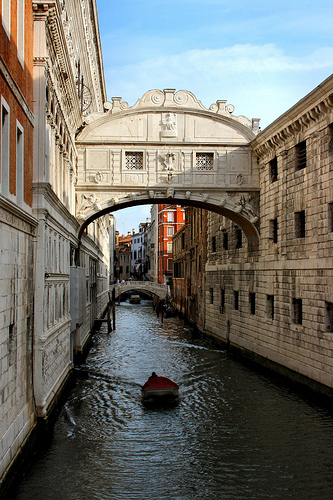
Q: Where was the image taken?
A: It was taken at the city.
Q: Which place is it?
A: It is a city.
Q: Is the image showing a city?
A: Yes, it is showing a city.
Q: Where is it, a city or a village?
A: It is a city.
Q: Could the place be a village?
A: No, it is a city.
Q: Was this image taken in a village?
A: No, the picture was taken in a city.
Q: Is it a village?
A: No, it is a city.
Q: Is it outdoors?
A: Yes, it is outdoors.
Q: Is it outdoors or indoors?
A: It is outdoors.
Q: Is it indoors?
A: No, it is outdoors.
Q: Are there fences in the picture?
A: No, there are no fences.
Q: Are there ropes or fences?
A: No, there are no fences or ropes.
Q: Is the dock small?
A: Yes, the dock is small.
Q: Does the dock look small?
A: Yes, the dock is small.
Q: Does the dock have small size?
A: Yes, the dock is small.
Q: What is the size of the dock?
A: The dock is small.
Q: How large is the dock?
A: The dock is small.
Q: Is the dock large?
A: No, the dock is small.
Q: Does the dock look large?
A: No, the dock is small.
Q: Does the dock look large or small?
A: The dock is small.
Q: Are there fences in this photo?
A: No, there are no fences.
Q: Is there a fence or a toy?
A: No, there are no fences or toys.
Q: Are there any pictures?
A: No, there are no pictures.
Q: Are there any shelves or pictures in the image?
A: No, there are no pictures or shelves.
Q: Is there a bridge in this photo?
A: Yes, there is a bridge.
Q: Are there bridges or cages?
A: Yes, there is a bridge.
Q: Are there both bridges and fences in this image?
A: No, there is a bridge but no fences.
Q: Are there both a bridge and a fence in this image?
A: No, there is a bridge but no fences.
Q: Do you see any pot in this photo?
A: No, there are no pots.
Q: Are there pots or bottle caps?
A: No, there are no pots or bottle caps.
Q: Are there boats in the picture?
A: Yes, there is a boat.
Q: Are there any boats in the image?
A: Yes, there is a boat.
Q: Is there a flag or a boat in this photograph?
A: Yes, there is a boat.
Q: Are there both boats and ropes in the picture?
A: No, there is a boat but no ropes.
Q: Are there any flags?
A: No, there are no flags.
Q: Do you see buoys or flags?
A: No, there are no flags or buoys.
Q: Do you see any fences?
A: No, there are no fences.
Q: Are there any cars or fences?
A: No, there are no fences or cars.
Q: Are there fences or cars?
A: No, there are no fences or cars.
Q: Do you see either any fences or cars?
A: No, there are no fences or cars.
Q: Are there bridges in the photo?
A: Yes, there is a bridge.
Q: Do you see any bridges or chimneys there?
A: Yes, there is a bridge.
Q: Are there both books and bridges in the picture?
A: No, there is a bridge but no books.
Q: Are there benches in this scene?
A: No, there are no benches.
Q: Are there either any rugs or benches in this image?
A: No, there are no benches or rugs.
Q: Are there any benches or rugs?
A: No, there are no benches or rugs.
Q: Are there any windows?
A: Yes, there are windows.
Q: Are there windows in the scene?
A: Yes, there are windows.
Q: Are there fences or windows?
A: Yes, there are windows.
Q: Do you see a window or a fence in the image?
A: Yes, there are windows.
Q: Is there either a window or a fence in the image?
A: Yes, there are windows.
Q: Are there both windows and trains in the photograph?
A: No, there are windows but no trains.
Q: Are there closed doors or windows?
A: Yes, there are closed windows.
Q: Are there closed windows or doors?
A: Yes, there are closed windows.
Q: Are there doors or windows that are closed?
A: Yes, the windows are closed.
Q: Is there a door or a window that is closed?
A: Yes, the windows are closed.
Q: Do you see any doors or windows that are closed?
A: Yes, the windows are closed.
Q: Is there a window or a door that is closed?
A: Yes, the windows are closed.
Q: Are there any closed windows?
A: Yes, there are closed windows.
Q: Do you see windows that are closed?
A: Yes, there are windows that are closed.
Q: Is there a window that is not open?
A: Yes, there are closed windows.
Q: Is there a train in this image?
A: No, there are no trains.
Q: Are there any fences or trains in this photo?
A: No, there are no trains or fences.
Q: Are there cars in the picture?
A: No, there are no cars.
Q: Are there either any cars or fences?
A: No, there are no cars or fences.